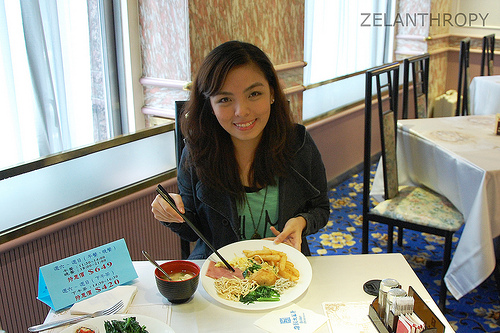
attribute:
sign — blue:
[66, 269, 119, 284]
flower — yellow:
[318, 227, 357, 251]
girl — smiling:
[144, 33, 333, 260]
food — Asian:
[206, 259, 243, 279]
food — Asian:
[239, 285, 279, 302]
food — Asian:
[243, 244, 300, 282]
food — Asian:
[250, 270, 275, 285]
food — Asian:
[215, 254, 295, 301]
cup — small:
[152, 255, 204, 305]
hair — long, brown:
[156, 38, 291, 163]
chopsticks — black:
[158, 181, 235, 271]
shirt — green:
[218, 172, 308, 251]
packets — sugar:
[394, 310, 424, 330]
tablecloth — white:
[369, 112, 499, 301]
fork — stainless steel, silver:
[24, 298, 124, 331]